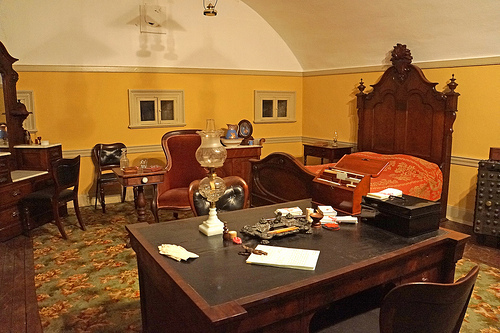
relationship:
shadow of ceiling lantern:
[124, 1, 181, 69] [197, 3, 220, 20]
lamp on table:
[190, 114, 232, 239] [121, 178, 469, 324]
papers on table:
[246, 244, 321, 271] [121, 178, 469, 324]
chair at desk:
[381, 265, 481, 331] [124, 198, 471, 333]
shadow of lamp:
[119, 22, 185, 67] [194, 130, 227, 237]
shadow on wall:
[119, 22, 185, 67] [0, 18, 317, 204]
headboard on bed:
[335, 36, 453, 185] [237, 81, 474, 209]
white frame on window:
[122, 83, 200, 133] [122, 83, 199, 130]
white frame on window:
[248, 83, 313, 127] [245, 87, 297, 128]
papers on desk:
[243, 242, 320, 272] [124, 198, 471, 333]